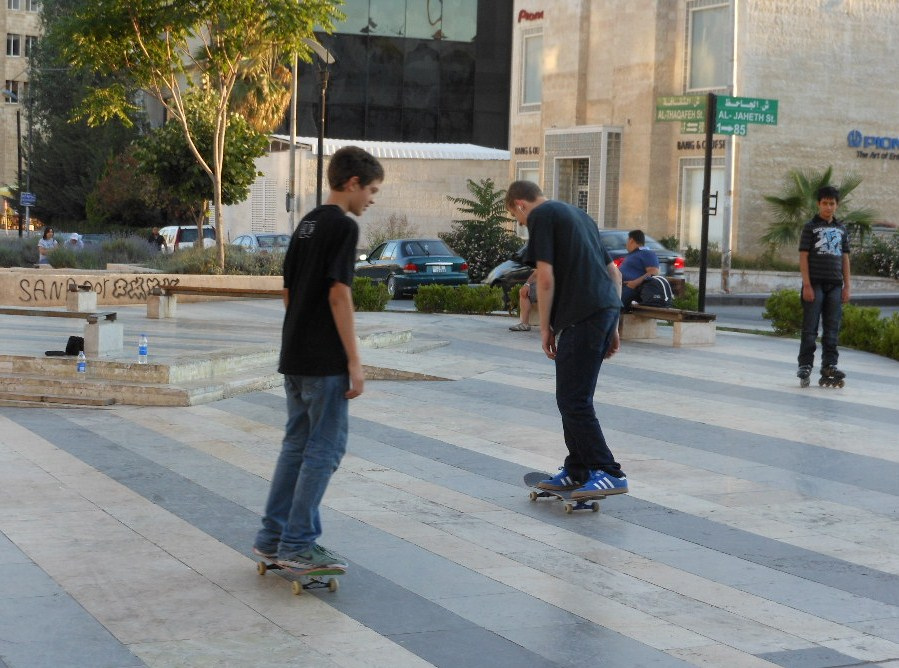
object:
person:
[617, 230, 660, 310]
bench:
[617, 274, 717, 347]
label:
[138, 347, 148, 356]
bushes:
[414, 283, 505, 314]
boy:
[505, 180, 628, 498]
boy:
[620, 229, 661, 313]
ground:
[1, 311, 899, 663]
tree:
[54, 0, 344, 274]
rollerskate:
[797, 357, 815, 388]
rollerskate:
[817, 361, 846, 388]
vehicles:
[354, 238, 469, 299]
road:
[343, 290, 899, 360]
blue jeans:
[253, 374, 348, 561]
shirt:
[278, 205, 360, 377]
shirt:
[798, 213, 851, 286]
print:
[813, 226, 845, 256]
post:
[698, 92, 719, 316]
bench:
[0, 307, 124, 358]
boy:
[253, 144, 382, 569]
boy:
[797, 186, 852, 387]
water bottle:
[138, 334, 149, 365]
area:
[0, 305, 899, 661]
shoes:
[538, 466, 629, 499]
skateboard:
[523, 472, 607, 514]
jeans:
[556, 306, 622, 479]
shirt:
[521, 200, 623, 337]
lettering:
[656, 94, 778, 136]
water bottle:
[75, 351, 86, 383]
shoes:
[253, 543, 348, 570]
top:
[799, 189, 852, 281]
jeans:
[798, 284, 844, 368]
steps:
[0, 322, 450, 408]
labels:
[77, 362, 87, 373]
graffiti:
[18, 277, 180, 302]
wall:
[0, 271, 284, 308]